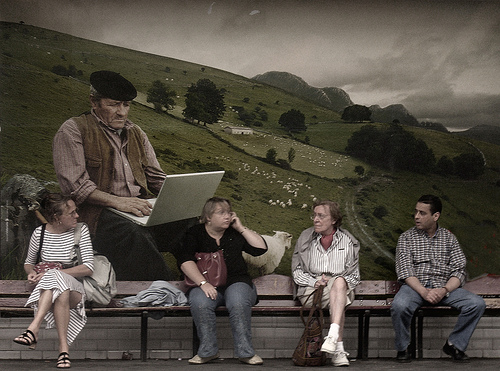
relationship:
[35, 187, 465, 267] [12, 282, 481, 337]
people on bench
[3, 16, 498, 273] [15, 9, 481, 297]
mural on wall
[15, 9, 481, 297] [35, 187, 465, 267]
wall behind people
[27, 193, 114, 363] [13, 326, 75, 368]
woman wearing heels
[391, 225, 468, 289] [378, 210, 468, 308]
man wearing shirt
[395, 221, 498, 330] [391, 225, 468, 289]
shirt on man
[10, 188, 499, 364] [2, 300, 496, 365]
four people sit on bench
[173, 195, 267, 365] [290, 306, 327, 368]
woman holding bag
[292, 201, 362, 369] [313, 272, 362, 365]
women has legs crossed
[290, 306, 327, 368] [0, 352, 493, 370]
bag on ground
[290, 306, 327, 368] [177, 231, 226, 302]
bag under womans arm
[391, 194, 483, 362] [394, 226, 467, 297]
man wears checked shirt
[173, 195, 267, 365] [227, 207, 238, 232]
woman talks on cell phone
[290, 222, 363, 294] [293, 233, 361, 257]
gray jacket worn over shoulders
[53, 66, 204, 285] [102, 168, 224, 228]
man uses a computer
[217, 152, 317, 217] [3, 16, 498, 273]
sheep are in mural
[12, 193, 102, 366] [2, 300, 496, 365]
lady sits on bench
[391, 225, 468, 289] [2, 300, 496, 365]
man sits on bench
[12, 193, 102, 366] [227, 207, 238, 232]
lady holding cell phone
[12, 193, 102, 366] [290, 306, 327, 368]
lady holding brown bag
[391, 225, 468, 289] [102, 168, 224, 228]
man using a computer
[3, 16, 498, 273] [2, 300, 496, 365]
mural was painted behind bench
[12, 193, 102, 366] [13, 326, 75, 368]
lady wears open sandals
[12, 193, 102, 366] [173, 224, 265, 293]
lady wearing a black shirt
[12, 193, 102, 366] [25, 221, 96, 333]
lady wearing a striped dress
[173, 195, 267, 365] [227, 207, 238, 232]
woman holding cell phone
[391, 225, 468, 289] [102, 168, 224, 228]
man uses a computer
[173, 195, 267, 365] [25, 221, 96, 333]
woman wearing a striped dress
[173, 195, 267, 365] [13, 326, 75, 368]
woman wearing sandals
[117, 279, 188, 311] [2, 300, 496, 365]
clothing sits on bench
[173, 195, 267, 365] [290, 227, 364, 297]
woman wearing a striped shirt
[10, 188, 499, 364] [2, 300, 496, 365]
four people sitting on bench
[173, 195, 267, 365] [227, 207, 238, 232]
woman using a cell phone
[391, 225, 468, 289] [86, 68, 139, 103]
man wearing black beret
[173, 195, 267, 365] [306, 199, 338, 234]
woman facing left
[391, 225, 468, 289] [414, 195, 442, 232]
man facing left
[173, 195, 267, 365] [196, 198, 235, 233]
woman facing right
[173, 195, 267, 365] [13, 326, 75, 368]
woman wearing black sandals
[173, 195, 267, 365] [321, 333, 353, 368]
woman wearing white sneakers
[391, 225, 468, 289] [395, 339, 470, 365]
man wearing black shoes